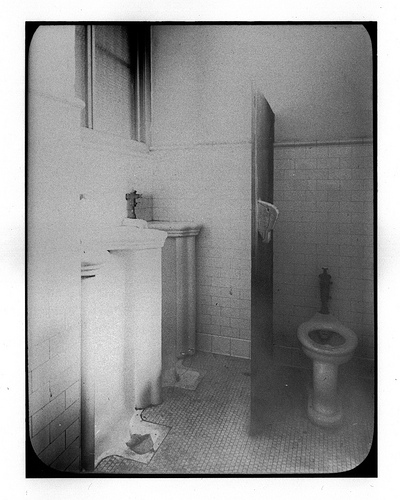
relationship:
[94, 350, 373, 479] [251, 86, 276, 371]
bathroom floor on wall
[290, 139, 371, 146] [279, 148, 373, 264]
edge of tile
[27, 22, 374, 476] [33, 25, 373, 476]
image for magazine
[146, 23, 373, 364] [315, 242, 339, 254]
wall are brick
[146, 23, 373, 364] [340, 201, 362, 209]
wall are brick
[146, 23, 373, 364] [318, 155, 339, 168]
wall are brick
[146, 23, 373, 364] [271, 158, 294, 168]
wall are brick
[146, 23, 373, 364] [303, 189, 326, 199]
wall are brick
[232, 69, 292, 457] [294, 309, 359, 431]
divider beside toilet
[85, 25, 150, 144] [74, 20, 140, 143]
blinds with blinds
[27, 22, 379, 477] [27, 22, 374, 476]
border bordering image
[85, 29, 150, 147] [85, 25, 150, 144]
blinds covering blinds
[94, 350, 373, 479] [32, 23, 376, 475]
bathroom floor for restroom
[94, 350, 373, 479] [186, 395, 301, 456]
bathroom floor made of tiles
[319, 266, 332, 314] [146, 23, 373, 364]
pipe connected to wall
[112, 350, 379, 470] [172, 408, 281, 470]
tiles on floor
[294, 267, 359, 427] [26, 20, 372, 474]
toilet on wall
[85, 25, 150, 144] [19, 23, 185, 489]
blinds on wall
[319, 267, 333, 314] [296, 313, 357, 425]
pipe behind toilet